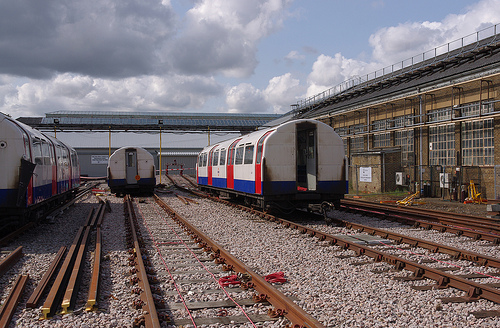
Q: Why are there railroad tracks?
A: For the train to travel on.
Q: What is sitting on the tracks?
A: A train.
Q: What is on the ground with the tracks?
A: Gravel.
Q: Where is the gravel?
A: On the tracks.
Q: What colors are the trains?
A: Red, white and blue.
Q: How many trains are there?
A: Three.